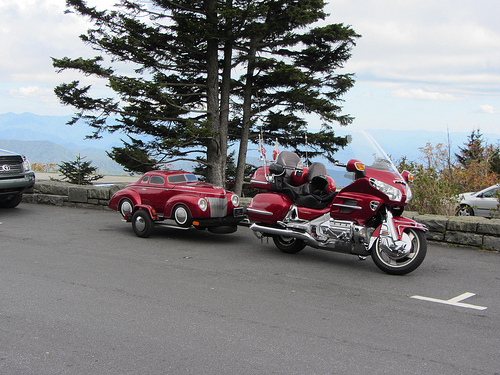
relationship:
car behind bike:
[107, 169, 248, 238] [246, 141, 430, 277]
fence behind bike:
[22, 179, 499, 252] [253, 147, 423, 272]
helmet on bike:
[302, 170, 345, 207] [246, 127, 426, 275]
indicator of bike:
[354, 161, 366, 171] [246, 127, 426, 275]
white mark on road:
[408, 290, 488, 311] [3, 195, 495, 373]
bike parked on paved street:
[246, 141, 430, 277] [0, 200, 499, 373]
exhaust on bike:
[254, 222, 314, 242] [246, 141, 430, 277]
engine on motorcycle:
[309, 217, 364, 239] [234, 157, 428, 270]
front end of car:
[0, 146, 40, 200] [435, 173, 492, 212]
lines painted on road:
[409, 291, 487, 311] [3, 195, 495, 373]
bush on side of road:
[56, 152, 106, 183] [3, 195, 495, 373]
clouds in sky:
[1, 1, 498, 133] [1, 1, 496, 168]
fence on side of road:
[22, 179, 499, 252] [3, 195, 495, 373]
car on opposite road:
[440, 179, 500, 220] [3, 195, 495, 373]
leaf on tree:
[65, 117, 79, 126] [50, 1, 362, 200]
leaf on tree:
[85, 134, 93, 141] [50, 1, 362, 200]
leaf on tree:
[95, 54, 105, 61] [50, 1, 362, 200]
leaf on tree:
[133, 67, 145, 73] [50, 1, 362, 200]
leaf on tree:
[114, 117, 125, 123] [50, 1, 362, 200]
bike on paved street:
[246, 127, 426, 275] [0, 200, 499, 373]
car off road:
[440, 174, 497, 226] [3, 195, 495, 373]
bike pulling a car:
[246, 141, 430, 277] [107, 169, 243, 244]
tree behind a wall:
[46, 151, 105, 187] [12, 174, 496, 251]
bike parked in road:
[246, 141, 430, 277] [3, 195, 495, 373]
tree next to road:
[53, 0, 408, 187] [3, 195, 495, 373]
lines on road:
[399, 282, 493, 340] [3, 195, 495, 373]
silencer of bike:
[250, 223, 322, 244] [253, 147, 423, 272]